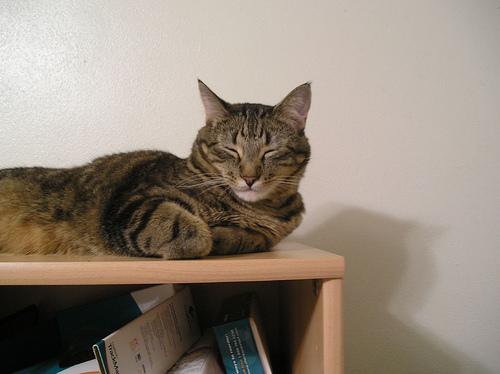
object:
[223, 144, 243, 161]
eye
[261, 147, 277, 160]
eye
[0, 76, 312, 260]
cat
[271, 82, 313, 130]
ear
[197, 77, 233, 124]
ear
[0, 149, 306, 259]
body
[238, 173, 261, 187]
nose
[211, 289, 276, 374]
box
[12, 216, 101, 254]
belly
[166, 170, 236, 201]
whiskers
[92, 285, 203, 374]
books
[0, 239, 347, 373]
bookcase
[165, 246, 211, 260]
cat paws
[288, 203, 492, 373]
shadow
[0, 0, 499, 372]
wall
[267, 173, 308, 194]
white whiskers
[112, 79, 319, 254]
black stripes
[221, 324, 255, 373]
words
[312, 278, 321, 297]
metal bracket